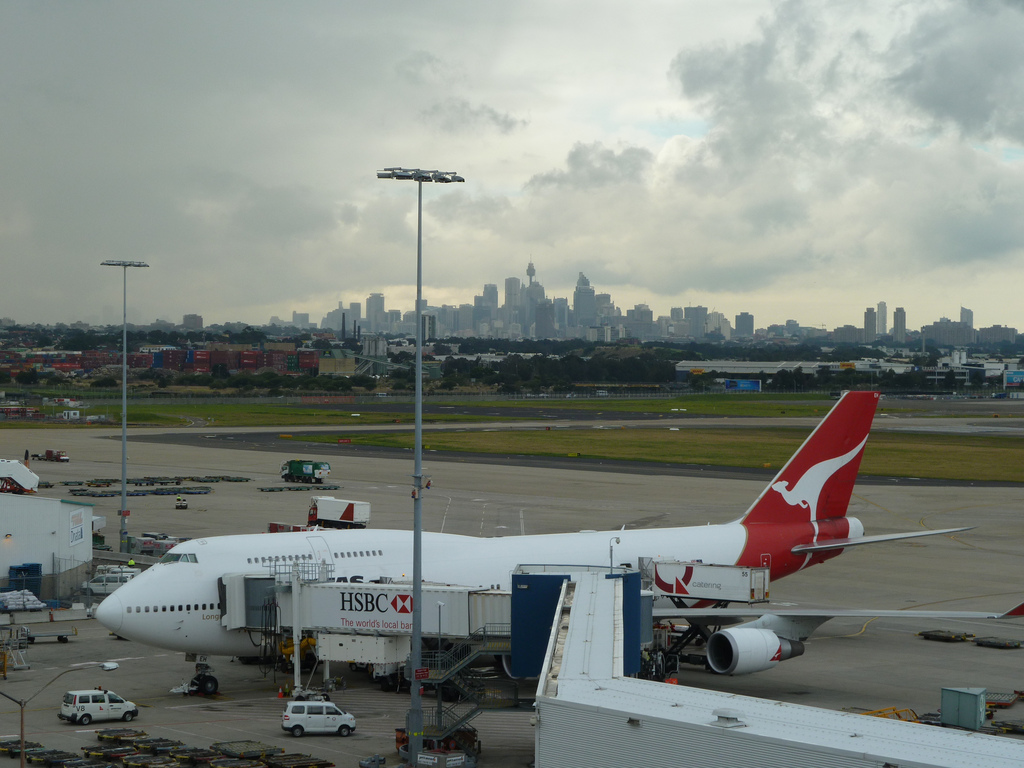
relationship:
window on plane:
[165, 552, 178, 561] [68, 397, 951, 683]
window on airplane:
[179, 543, 196, 564] [96, 391, 1024, 675]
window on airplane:
[109, 599, 138, 616] [96, 391, 1024, 675]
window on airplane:
[127, 603, 144, 616] [96, 391, 1024, 675]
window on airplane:
[151, 600, 161, 608] [96, 391, 1024, 675]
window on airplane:
[153, 603, 179, 620] [96, 391, 1024, 675]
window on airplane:
[175, 599, 192, 622] [96, 391, 1024, 675]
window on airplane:
[169, 599, 201, 612] [96, 391, 1024, 675]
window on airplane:
[191, 603, 201, 613] [96, 391, 1024, 675]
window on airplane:
[125, 608, 139, 627] [96, 391, 1024, 675]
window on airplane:
[153, 605, 157, 621] [96, 391, 1024, 675]